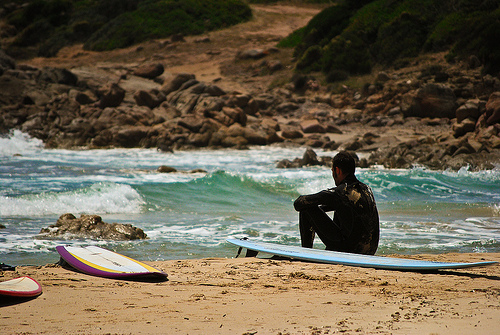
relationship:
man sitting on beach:
[294, 150, 378, 252] [0, 250, 500, 331]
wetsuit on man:
[295, 176, 380, 256] [294, 150, 378, 252]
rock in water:
[37, 208, 147, 248] [0, 123, 500, 269]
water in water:
[0, 134, 499, 255] [0, 123, 500, 269]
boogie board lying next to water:
[55, 243, 170, 283] [0, 123, 500, 269]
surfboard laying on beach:
[223, 232, 498, 270] [0, 250, 500, 331]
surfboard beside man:
[223, 232, 498, 270] [294, 150, 378, 252]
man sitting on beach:
[294, 150, 378, 252] [3, 256, 493, 332]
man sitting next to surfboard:
[294, 150, 378, 252] [228, 235, 497, 273]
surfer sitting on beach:
[294, 150, 379, 253] [0, 250, 500, 331]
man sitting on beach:
[294, 150, 378, 252] [3, 256, 499, 334]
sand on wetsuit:
[342, 182, 374, 206] [295, 176, 380, 256]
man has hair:
[294, 150, 378, 252] [330, 150, 355, 177]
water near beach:
[0, 123, 500, 269] [0, 250, 500, 331]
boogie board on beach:
[55, 243, 171, 281] [0, 250, 500, 331]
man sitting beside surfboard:
[294, 150, 378, 252] [228, 235, 497, 273]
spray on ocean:
[1, 125, 46, 156] [0, 148, 499, 263]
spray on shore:
[1, 125, 46, 156] [1, 1, 499, 171]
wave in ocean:
[0, 179, 155, 223] [0, 129, 499, 267]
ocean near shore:
[0, 129, 499, 267] [1, 1, 499, 171]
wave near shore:
[0, 179, 155, 223] [2, 252, 499, 333]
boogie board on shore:
[55, 243, 171, 281] [2, 252, 499, 333]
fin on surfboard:
[235, 246, 258, 257] [231, 237, 495, 271]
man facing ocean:
[294, 150, 378, 252] [0, 129, 499, 267]